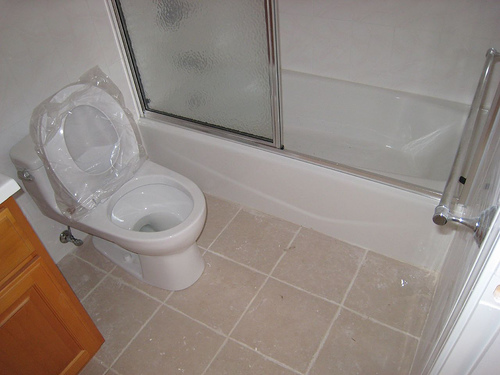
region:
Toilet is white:
[46, 84, 218, 291]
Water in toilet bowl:
[135, 209, 180, 236]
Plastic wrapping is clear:
[44, 89, 139, 189]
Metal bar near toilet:
[442, 44, 478, 251]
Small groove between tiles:
[236, 224, 303, 314]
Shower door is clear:
[113, 5, 293, 162]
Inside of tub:
[293, 75, 471, 183]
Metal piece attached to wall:
[55, 226, 86, 254]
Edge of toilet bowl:
[106, 224, 172, 253]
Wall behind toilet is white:
[6, 8, 110, 74]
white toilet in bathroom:
[21, 82, 230, 296]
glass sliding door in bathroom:
[155, 1, 328, 173]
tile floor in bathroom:
[274, 225, 347, 307]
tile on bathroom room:
[252, 297, 318, 360]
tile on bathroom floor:
[156, 305, 204, 370]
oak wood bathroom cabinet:
[1, 227, 109, 353]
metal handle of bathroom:
[438, 60, 493, 255]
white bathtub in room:
[315, 70, 441, 212]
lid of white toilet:
[36, 92, 150, 177]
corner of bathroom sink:
[0, 182, 30, 207]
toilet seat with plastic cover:
[29, 43, 164, 215]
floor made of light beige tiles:
[215, 224, 400, 361]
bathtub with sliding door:
[108, 3, 485, 234]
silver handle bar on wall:
[430, 39, 499, 286]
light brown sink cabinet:
[2, 178, 119, 373]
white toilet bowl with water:
[1, 66, 222, 313]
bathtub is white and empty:
[108, 19, 474, 249]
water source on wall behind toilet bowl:
[25, 181, 132, 275]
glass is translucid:
[104, 1, 324, 170]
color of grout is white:
[243, 233, 402, 373]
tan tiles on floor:
[91, 252, 396, 358]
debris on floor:
[55, 256, 280, 370]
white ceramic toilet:
[8, 82, 230, 285]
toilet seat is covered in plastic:
[18, 72, 155, 217]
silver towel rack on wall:
[416, 41, 496, 248]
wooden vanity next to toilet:
[9, 211, 117, 365]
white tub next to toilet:
[220, 43, 437, 273]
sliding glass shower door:
[117, 0, 289, 162]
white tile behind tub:
[332, 10, 445, 86]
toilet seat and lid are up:
[19, 70, 152, 204]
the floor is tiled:
[248, 260, 353, 348]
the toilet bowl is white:
[6, 105, 251, 291]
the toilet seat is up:
[30, 64, 176, 201]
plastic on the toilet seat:
[21, 85, 175, 187]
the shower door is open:
[108, 1, 312, 153]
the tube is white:
[315, 99, 454, 168]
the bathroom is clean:
[8, 5, 491, 368]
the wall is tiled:
[368, 14, 462, 82]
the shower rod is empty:
[427, 50, 499, 229]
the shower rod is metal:
[430, 49, 497, 218]